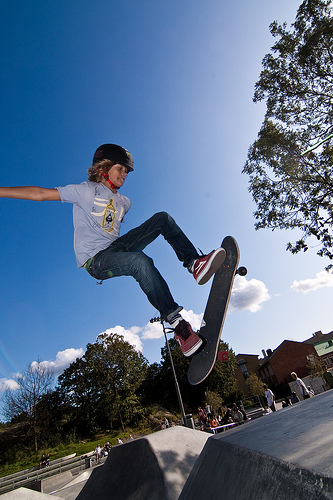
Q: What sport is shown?
A: Skateboarding.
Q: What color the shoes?
A: Red.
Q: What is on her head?
A: Helmet.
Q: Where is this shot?
A: Skate park.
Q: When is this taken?
A: Daytime.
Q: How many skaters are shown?
A: 1.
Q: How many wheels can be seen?
A: 2.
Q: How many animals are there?
A: 0.